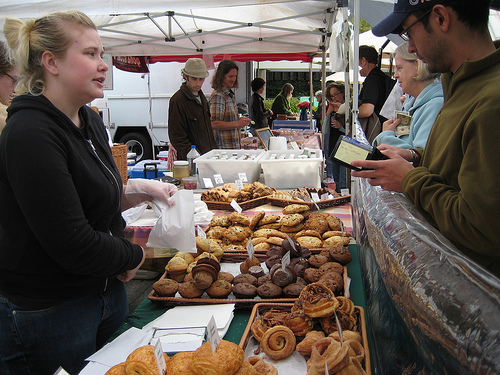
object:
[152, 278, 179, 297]
muffin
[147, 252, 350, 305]
tray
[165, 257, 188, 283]
muffin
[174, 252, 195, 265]
muffin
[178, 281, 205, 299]
muffin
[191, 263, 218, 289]
muffin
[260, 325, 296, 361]
donut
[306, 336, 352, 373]
donut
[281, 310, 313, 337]
donut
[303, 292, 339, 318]
donut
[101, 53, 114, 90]
sign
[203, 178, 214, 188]
sign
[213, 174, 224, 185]
sign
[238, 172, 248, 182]
sign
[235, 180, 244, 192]
sign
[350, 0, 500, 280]
man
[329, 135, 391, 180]
wallet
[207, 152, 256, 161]
goods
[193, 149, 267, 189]
container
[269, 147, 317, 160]
goods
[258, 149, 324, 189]
container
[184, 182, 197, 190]
goods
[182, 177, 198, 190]
container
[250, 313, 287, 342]
donut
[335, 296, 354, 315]
donut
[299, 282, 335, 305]
donut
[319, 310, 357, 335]
donut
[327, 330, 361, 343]
donut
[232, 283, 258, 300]
muffin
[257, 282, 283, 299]
muffin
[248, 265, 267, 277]
muffin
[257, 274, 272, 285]
muffin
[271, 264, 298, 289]
muffin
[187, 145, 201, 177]
drink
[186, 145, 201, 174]
bottle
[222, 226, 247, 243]
cookie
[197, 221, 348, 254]
tray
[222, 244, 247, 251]
cookie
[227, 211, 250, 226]
cookie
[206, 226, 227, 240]
cookie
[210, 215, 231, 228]
cookie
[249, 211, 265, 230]
cookie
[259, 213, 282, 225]
cookie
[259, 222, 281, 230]
cookie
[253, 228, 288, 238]
cookie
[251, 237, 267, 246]
cookie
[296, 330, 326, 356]
donut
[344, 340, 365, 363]
donut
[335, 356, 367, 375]
donut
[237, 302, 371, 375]
tray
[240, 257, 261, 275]
muffin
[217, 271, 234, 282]
muffin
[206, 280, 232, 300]
muffin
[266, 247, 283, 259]
muffin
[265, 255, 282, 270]
muffin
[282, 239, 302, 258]
muffin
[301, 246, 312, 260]
muffin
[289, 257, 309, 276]
muffin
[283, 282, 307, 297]
muffin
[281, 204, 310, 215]
cookie